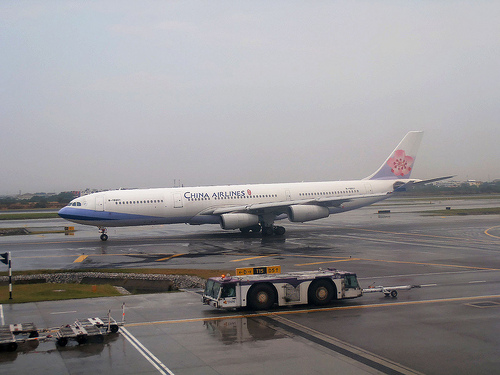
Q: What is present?
A: A plane.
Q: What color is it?
A: White.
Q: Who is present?
A: Nobody.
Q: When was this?
A: Daytime.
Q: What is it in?
A: An airport.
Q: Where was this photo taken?
A: At an airport terminal.